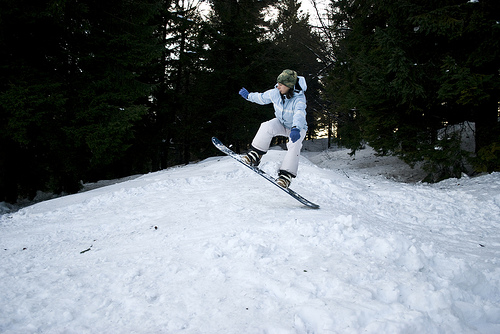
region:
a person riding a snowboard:
[214, 55, 335, 237]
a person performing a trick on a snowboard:
[222, 70, 328, 218]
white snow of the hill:
[146, 230, 309, 307]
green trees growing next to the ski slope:
[2, 15, 197, 164]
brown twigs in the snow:
[51, 222, 163, 271]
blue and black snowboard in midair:
[203, 136, 320, 212]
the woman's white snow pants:
[248, 122, 315, 184]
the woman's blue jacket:
[251, 83, 322, 138]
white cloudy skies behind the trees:
[291, 0, 337, 27]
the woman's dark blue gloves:
[236, 88, 302, 140]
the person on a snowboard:
[210, 68, 320, 208]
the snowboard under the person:
[210, 133, 321, 210]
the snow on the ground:
[0, 137, 497, 333]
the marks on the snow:
[1, 120, 497, 332]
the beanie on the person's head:
[275, 68, 297, 89]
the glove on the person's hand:
[239, 87, 250, 97]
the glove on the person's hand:
[288, 126, 299, 139]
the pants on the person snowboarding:
[250, 117, 306, 178]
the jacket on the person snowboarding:
[245, 73, 305, 133]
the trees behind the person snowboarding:
[0, 0, 499, 215]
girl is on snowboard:
[230, 62, 326, 192]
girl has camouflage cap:
[276, 64, 297, 91]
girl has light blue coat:
[254, 84, 316, 127]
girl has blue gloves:
[220, 79, 303, 145]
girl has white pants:
[249, 106, 313, 171]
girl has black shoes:
[236, 144, 297, 189]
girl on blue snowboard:
[212, 137, 333, 217]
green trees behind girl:
[156, 1, 459, 167]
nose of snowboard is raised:
[190, 118, 309, 237]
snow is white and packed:
[90, 169, 416, 274]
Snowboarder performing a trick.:
[211, 68, 321, 210]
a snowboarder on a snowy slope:
[191, 60, 326, 227]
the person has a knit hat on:
[274, 65, 300, 92]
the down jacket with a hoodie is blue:
[246, 73, 311, 128]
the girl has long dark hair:
[275, 78, 297, 101]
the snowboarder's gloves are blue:
[235, 84, 303, 145]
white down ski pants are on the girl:
[248, 118, 307, 176]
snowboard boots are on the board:
[243, 148, 293, 192]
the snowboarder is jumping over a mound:
[45, 65, 495, 324]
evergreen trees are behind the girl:
[4, 5, 496, 234]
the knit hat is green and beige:
[273, 65, 307, 95]